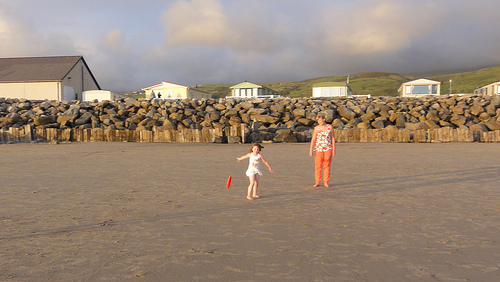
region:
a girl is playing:
[217, 137, 279, 202]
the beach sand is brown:
[27, 208, 482, 274]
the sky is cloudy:
[99, 7, 489, 67]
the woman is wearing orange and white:
[300, 110, 350, 189]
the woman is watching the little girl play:
[194, 107, 354, 208]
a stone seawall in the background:
[20, 97, 303, 127]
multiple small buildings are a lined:
[12, 57, 491, 99]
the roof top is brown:
[7, 53, 102, 84]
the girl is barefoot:
[246, 183, 272, 208]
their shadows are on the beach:
[380, 162, 493, 197]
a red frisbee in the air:
[217, 174, 240, 195]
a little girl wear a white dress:
[236, 136, 279, 198]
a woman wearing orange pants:
[297, 107, 345, 198]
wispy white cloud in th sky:
[169, 13, 234, 50]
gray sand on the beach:
[67, 170, 129, 205]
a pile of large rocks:
[80, 111, 177, 127]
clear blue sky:
[104, 11, 186, 28]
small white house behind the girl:
[132, 73, 227, 96]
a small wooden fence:
[381, 125, 435, 145]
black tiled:
[43, 57, 55, 78]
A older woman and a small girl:
[206, 95, 363, 213]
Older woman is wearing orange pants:
[310, 138, 351, 198]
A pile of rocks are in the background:
[5, 95, 497, 126]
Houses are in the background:
[130, 68, 496, 114]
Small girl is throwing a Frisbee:
[206, 132, 286, 215]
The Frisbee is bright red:
[202, 161, 243, 201]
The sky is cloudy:
[5, 3, 495, 63]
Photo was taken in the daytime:
[17, 10, 492, 276]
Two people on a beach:
[93, 105, 460, 251]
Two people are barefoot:
[227, 169, 369, 222]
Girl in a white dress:
[225, 133, 350, 198]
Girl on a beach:
[220, 133, 284, 204]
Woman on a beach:
[296, 105, 363, 192]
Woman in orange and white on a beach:
[304, 98, 351, 198]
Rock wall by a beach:
[83, 91, 395, 158]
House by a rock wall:
[218, 79, 291, 106]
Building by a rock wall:
[3, 49, 99, 129]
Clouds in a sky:
[173, 3, 348, 88]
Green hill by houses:
[293, 61, 449, 126]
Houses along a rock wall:
[137, 72, 453, 112]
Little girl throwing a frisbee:
[215, 137, 280, 211]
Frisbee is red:
[218, 167, 238, 191]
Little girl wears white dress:
[232, 138, 283, 209]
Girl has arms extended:
[235, 138, 277, 205]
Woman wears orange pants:
[301, 105, 342, 193]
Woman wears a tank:
[297, 108, 347, 196]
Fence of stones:
[7, 92, 497, 134]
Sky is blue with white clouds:
[2, 4, 497, 58]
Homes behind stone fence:
[0, 47, 495, 99]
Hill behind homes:
[192, 64, 497, 95]